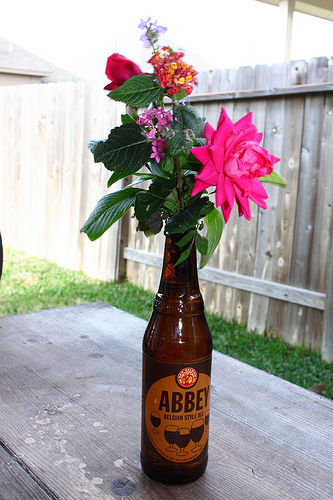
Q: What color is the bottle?
A: Brown.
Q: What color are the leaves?
A: Green.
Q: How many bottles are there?
A: One.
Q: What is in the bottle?
A: A bouquet of flowers.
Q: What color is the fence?
A: Light brown.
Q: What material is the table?
A: Wood.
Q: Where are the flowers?
A: In the bottle.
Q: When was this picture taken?
A: Daytime.